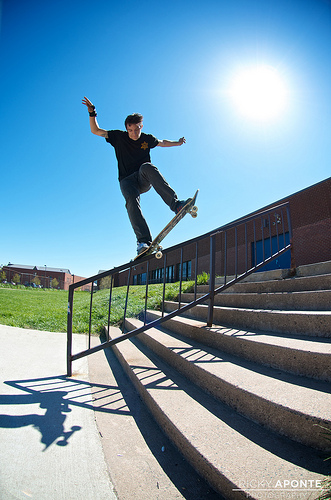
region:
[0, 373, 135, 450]
a shadow of the skateboarder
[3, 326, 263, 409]
a shadow of the safety guard rail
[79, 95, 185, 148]
the skateboarder is using his arms for balance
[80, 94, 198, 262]
a skateboarder grinding on a handrail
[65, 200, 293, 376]
bronze aluminum safety handrail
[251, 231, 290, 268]
blue warehouse double doors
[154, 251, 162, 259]
white polyurethane skateboard wheel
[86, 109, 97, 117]
the skateboarder is wearing a wrist watch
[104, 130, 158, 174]
the skateboarder is wearing a black t-shirt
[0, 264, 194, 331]
a grass field behind the skateboarder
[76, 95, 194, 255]
a male skateboarder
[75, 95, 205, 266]
a man on a skateboard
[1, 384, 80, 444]
shadow of man on skateboard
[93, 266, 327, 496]
a short stair case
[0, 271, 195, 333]
a patch of green grass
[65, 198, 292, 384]
a black metal railing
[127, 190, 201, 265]
a white and black skateboard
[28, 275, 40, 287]
a green tree in distance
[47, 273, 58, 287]
a green tree in distance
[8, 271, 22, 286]
a green tree in distance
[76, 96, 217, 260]
Teenage boy skating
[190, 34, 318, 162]
sun in the sky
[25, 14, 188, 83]
There are no clouds in the sky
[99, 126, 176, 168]
black shirt with a gold star of david in the upper right corner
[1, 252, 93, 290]
building in the background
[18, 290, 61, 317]
Cut green grass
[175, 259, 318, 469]
Concrete stairs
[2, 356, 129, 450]
Shadow of the teenager skating on the railing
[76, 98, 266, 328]
Teenage boy skating on a rail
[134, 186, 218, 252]
Skateboard with white tires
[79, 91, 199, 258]
the man doing a trick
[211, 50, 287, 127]
the sun is shining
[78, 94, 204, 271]
the man on the skateboard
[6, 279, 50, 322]
the grass is green and sloping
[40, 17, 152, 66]
the sky is blue and clear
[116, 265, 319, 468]
the steps are concrete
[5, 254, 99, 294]
the brick building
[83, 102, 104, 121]
the wrist guard on the wrist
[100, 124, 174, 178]
the boy wearing a t shirt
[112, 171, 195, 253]
the boy wearing jeans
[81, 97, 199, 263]
Boy riding rail on skateboard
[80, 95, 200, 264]
boy wearing black shirt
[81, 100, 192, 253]
boy wearing grey pants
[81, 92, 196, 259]
boy wearing black wrist guard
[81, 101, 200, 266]
boy has brown hair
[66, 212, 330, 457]
railing on cement steps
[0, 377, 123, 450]
shadow on cement walkway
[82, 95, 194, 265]
Boy wearing short sleeve shirt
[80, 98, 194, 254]
boy wearing long pants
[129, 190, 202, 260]
skateboard has white wheels